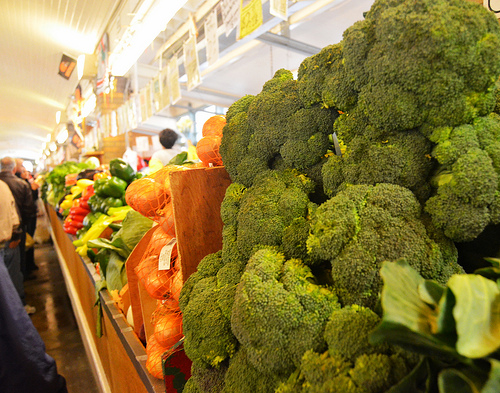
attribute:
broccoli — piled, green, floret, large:
[226, 243, 336, 375]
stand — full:
[38, 170, 220, 391]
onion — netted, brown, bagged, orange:
[122, 176, 169, 217]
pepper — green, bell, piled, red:
[101, 177, 128, 197]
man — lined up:
[1, 153, 37, 288]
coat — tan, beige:
[0, 181, 22, 242]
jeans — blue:
[0, 237, 30, 310]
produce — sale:
[37, 2, 498, 389]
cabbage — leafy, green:
[95, 245, 130, 290]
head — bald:
[0, 156, 19, 175]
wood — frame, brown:
[166, 161, 231, 277]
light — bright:
[107, 0, 179, 81]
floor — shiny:
[26, 238, 99, 392]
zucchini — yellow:
[77, 177, 98, 191]